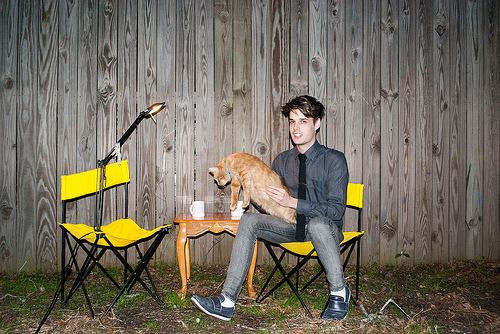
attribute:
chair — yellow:
[60, 159, 170, 317]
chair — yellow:
[259, 183, 362, 321]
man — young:
[191, 94, 352, 322]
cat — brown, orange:
[208, 150, 301, 223]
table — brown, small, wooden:
[175, 213, 261, 299]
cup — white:
[189, 201, 206, 220]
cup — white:
[230, 202, 245, 220]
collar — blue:
[223, 157, 233, 182]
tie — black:
[295, 153, 307, 244]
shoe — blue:
[190, 292, 237, 323]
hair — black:
[281, 94, 324, 120]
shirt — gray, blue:
[269, 140, 349, 232]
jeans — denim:
[221, 212, 347, 301]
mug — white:
[189, 200, 206, 219]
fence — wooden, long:
[1, 1, 498, 274]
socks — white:
[220, 291, 345, 310]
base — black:
[264, 241, 361, 320]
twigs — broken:
[5, 280, 414, 333]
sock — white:
[219, 292, 235, 311]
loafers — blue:
[191, 287, 354, 322]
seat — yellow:
[58, 216, 171, 251]